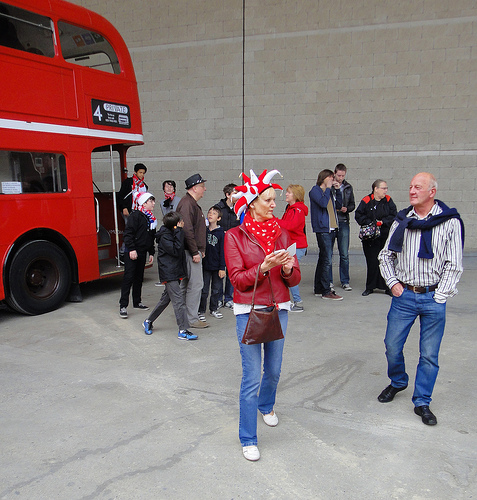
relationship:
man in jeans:
[376, 169, 466, 427] [385, 286, 446, 403]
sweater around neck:
[394, 199, 465, 254] [411, 203, 439, 217]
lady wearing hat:
[223, 168, 302, 464] [228, 170, 285, 221]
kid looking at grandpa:
[198, 208, 223, 321] [176, 174, 212, 331]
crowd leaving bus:
[117, 165, 464, 464] [3, 0, 145, 317]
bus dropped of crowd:
[3, 0, 145, 317] [117, 165, 464, 464]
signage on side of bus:
[89, 98, 131, 130] [3, 0, 145, 317]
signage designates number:
[89, 98, 131, 130] [92, 104, 104, 123]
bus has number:
[3, 0, 145, 317] [92, 104, 104, 123]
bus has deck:
[3, 0, 145, 317] [0, 144, 147, 288]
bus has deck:
[3, 0, 145, 317] [0, 0, 144, 137]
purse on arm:
[245, 267, 284, 348] [224, 234, 270, 295]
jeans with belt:
[385, 286, 446, 403] [400, 283, 436, 293]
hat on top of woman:
[228, 170, 285, 221] [223, 168, 302, 464]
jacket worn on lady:
[224, 224, 300, 305] [223, 168, 302, 464]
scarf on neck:
[246, 213, 282, 257] [249, 215, 271, 230]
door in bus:
[88, 140, 141, 275] [3, 0, 145, 317]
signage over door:
[89, 98, 131, 130] [88, 140, 141, 275]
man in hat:
[176, 174, 212, 331] [184, 174, 206, 188]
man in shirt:
[376, 169, 466, 427] [379, 205, 460, 303]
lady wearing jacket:
[223, 168, 302, 464] [224, 224, 300, 305]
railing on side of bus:
[90, 198, 102, 232] [3, 0, 145, 317]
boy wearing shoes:
[142, 214, 195, 341] [140, 320, 198, 341]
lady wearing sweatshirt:
[280, 187, 311, 305] [281, 201, 309, 250]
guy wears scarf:
[309, 165, 340, 298] [328, 190, 338, 229]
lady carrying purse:
[223, 168, 302, 464] [245, 267, 284, 348]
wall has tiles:
[73, 1, 476, 247] [238, 31, 476, 158]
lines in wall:
[237, 0, 250, 184] [73, 1, 476, 247]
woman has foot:
[223, 168, 302, 464] [241, 439, 260, 462]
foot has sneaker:
[241, 439, 260, 462] [242, 448, 260, 464]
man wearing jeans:
[376, 169, 466, 427] [385, 286, 446, 403]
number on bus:
[92, 104, 104, 123] [3, 0, 145, 317]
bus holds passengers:
[3, 0, 145, 317] [117, 165, 464, 464]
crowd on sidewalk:
[117, 165, 464, 464] [0, 253, 477, 499]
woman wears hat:
[223, 168, 302, 464] [228, 170, 285, 221]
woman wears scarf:
[223, 168, 302, 464] [246, 213, 282, 257]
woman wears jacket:
[223, 168, 302, 464] [224, 224, 300, 305]